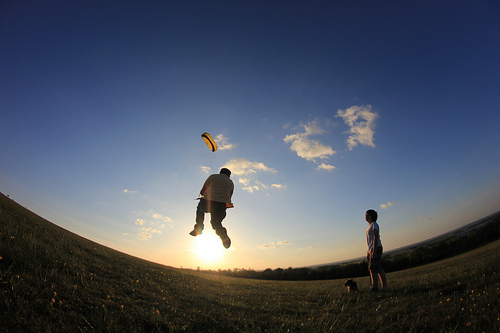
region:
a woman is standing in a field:
[358, 206, 398, 298]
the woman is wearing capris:
[366, 245, 386, 278]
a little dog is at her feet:
[337, 205, 397, 298]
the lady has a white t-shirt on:
[363, 222, 380, 252]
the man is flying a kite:
[178, 120, 245, 255]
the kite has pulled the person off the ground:
[178, 126, 240, 286]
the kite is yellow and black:
[194, 125, 224, 160]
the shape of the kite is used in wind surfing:
[196, 126, 221, 159]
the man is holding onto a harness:
[182, 163, 242, 243]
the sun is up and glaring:
[78, 51, 349, 268]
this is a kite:
[195, 127, 242, 166]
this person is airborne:
[183, 162, 252, 252]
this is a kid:
[350, 176, 410, 298]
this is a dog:
[341, 270, 371, 305]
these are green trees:
[198, 239, 353, 286]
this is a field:
[2, 180, 495, 332]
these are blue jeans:
[189, 186, 242, 250]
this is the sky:
[73, 52, 175, 157]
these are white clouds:
[288, 100, 430, 170]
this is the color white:
[305, 150, 308, 153]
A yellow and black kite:
[193, 131, 221, 153]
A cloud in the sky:
[264, 105, 384, 172]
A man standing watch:
[353, 206, 390, 295]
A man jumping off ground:
[184, 146, 244, 255]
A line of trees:
[245, 260, 365, 279]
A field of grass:
[60, 238, 117, 296]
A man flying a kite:
[168, 123, 250, 251]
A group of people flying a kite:
[176, 135, 400, 297]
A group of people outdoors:
[191, 123, 396, 293]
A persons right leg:
[376, 263, 389, 290]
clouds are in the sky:
[276, 103, 385, 172]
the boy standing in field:
[361, 206, 394, 296]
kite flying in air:
[196, 124, 227, 156]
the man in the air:
[187, 163, 239, 250]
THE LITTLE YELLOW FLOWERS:
[433, 273, 498, 330]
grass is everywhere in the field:
[2, 289, 499, 331]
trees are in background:
[253, 260, 349, 277]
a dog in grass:
[338, 276, 361, 299]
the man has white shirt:
[188, 165, 235, 249]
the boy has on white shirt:
[361, 205, 391, 297]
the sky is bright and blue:
[99, 52, 399, 321]